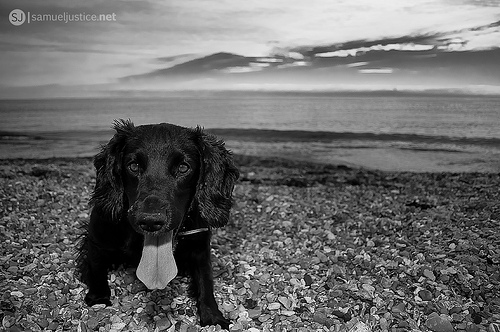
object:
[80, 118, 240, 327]
dog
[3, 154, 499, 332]
beach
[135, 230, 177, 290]
tongue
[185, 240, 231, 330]
leg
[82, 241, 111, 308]
leg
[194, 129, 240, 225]
ear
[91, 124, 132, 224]
ear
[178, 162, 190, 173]
eye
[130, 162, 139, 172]
eye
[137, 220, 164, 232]
nose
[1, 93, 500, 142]
water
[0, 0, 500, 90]
sky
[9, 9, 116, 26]
url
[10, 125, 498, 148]
wave